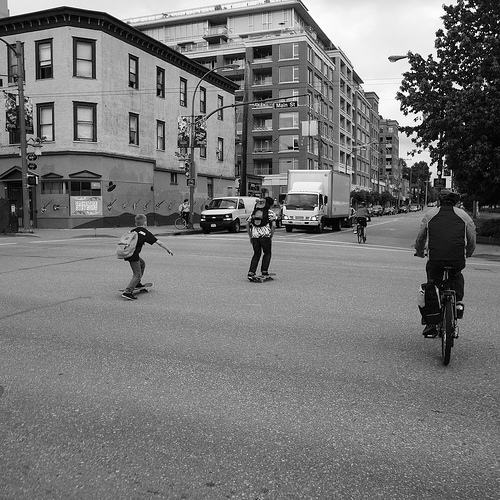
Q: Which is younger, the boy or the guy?
A: The boy is younger than the guy.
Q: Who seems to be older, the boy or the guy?
A: The guy is older than the boy.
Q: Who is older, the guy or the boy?
A: The guy is older than the boy.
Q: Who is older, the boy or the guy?
A: The guy is older than the boy.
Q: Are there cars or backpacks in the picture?
A: Yes, there is a backpack.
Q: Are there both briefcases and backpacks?
A: No, there is a backpack but no briefcases.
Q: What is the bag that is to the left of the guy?
A: The bag is a backpack.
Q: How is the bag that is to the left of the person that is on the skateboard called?
A: The bag is a backpack.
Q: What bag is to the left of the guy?
A: The bag is a backpack.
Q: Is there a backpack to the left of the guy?
A: Yes, there is a backpack to the left of the guy.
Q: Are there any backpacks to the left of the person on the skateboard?
A: Yes, there is a backpack to the left of the guy.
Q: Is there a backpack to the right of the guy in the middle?
A: No, the backpack is to the left of the guy.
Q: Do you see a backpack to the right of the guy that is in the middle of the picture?
A: No, the backpack is to the left of the guy.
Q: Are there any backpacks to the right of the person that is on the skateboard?
A: No, the backpack is to the left of the guy.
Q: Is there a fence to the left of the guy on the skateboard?
A: No, there is a backpack to the left of the guy.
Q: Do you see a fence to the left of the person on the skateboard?
A: No, there is a backpack to the left of the guy.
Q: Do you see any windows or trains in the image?
A: Yes, there is a window.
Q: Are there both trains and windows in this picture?
A: No, there is a window but no trains.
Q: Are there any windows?
A: Yes, there is a window.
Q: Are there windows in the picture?
A: Yes, there is a window.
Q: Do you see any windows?
A: Yes, there is a window.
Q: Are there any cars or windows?
A: Yes, there is a window.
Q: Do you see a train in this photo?
A: No, there are no trains.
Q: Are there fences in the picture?
A: No, there are no fences.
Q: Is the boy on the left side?
A: Yes, the boy is on the left of the image.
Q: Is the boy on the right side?
A: No, the boy is on the left of the image.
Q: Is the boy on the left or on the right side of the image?
A: The boy is on the left of the image.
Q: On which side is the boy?
A: The boy is on the left of the image.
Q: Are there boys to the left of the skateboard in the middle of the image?
A: Yes, there is a boy to the left of the skateboard.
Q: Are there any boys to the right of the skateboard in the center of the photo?
A: No, the boy is to the left of the skateboard.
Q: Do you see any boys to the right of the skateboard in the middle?
A: No, the boy is to the left of the skateboard.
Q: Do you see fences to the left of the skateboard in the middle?
A: No, there is a boy to the left of the skateboard.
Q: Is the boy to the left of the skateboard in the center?
A: Yes, the boy is to the left of the skateboard.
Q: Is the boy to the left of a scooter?
A: No, the boy is to the left of the skateboard.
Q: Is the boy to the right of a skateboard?
A: No, the boy is to the left of a skateboard.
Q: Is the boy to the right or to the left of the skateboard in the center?
A: The boy is to the left of the skateboard.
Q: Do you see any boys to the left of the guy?
A: Yes, there is a boy to the left of the guy.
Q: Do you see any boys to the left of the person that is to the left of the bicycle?
A: Yes, there is a boy to the left of the guy.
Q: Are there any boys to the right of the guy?
A: No, the boy is to the left of the guy.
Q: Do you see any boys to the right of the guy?
A: No, the boy is to the left of the guy.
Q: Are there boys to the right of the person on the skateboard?
A: No, the boy is to the left of the guy.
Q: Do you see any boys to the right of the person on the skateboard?
A: No, the boy is to the left of the guy.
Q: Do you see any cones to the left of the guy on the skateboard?
A: No, there is a boy to the left of the guy.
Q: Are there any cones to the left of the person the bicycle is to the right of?
A: No, there is a boy to the left of the guy.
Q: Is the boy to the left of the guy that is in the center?
A: Yes, the boy is to the left of the guy.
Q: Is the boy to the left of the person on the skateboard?
A: Yes, the boy is to the left of the guy.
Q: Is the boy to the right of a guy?
A: No, the boy is to the left of a guy.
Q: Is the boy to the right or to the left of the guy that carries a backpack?
A: The boy is to the left of the guy.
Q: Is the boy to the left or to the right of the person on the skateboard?
A: The boy is to the left of the guy.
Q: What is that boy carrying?
A: The boy is carrying a backpack.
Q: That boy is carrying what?
A: The boy is carrying a backpack.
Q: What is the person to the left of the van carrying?
A: The boy is carrying a backpack.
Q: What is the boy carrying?
A: The boy is carrying a backpack.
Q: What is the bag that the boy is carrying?
A: The bag is a backpack.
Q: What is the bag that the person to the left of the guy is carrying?
A: The bag is a backpack.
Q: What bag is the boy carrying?
A: The boy is carrying a backpack.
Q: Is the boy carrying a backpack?
A: Yes, the boy is carrying a backpack.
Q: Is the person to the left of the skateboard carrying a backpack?
A: Yes, the boy is carrying a backpack.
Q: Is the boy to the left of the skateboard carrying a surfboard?
A: No, the boy is carrying a backpack.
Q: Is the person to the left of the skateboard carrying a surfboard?
A: No, the boy is carrying a backpack.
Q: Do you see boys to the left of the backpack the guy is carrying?
A: Yes, there is a boy to the left of the backpack.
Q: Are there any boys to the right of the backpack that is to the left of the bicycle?
A: No, the boy is to the left of the backpack.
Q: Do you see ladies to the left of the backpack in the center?
A: No, there is a boy to the left of the backpack.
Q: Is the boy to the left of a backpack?
A: Yes, the boy is to the left of a backpack.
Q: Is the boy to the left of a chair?
A: No, the boy is to the left of a backpack.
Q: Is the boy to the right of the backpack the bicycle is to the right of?
A: No, the boy is to the left of the backpack.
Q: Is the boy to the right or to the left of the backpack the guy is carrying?
A: The boy is to the left of the backpack.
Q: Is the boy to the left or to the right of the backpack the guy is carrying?
A: The boy is to the left of the backpack.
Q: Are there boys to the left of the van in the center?
A: Yes, there is a boy to the left of the van.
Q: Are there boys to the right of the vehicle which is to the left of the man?
A: No, the boy is to the left of the van.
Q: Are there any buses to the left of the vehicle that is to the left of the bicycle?
A: No, there is a boy to the left of the van.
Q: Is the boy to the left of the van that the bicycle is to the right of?
A: Yes, the boy is to the left of the van.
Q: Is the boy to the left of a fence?
A: No, the boy is to the left of the van.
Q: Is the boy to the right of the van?
A: No, the boy is to the left of the van.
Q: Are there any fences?
A: No, there are no fences.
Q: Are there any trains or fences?
A: No, there are no fences or trains.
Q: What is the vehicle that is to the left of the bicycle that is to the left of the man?
A: The vehicle is a van.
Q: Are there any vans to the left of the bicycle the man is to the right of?
A: Yes, there is a van to the left of the bicycle.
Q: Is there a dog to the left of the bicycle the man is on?
A: No, there is a van to the left of the bicycle.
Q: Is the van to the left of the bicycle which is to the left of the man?
A: Yes, the van is to the left of the bicycle.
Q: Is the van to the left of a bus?
A: No, the van is to the left of the bicycle.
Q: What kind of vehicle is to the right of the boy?
A: The vehicle is a van.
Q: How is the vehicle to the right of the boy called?
A: The vehicle is a van.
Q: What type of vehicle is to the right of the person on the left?
A: The vehicle is a van.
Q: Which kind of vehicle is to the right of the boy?
A: The vehicle is a van.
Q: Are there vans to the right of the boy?
A: Yes, there is a van to the right of the boy.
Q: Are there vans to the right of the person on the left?
A: Yes, there is a van to the right of the boy.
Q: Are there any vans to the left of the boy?
A: No, the van is to the right of the boy.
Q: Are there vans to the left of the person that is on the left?
A: No, the van is to the right of the boy.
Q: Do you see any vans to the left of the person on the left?
A: No, the van is to the right of the boy.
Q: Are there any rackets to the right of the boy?
A: No, there is a van to the right of the boy.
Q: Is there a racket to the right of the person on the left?
A: No, there is a van to the right of the boy.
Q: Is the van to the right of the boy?
A: Yes, the van is to the right of the boy.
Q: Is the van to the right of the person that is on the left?
A: Yes, the van is to the right of the boy.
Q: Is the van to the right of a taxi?
A: No, the van is to the right of the boy.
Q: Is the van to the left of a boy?
A: No, the van is to the right of a boy.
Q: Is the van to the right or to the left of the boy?
A: The van is to the right of the boy.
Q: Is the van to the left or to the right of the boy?
A: The van is to the right of the boy.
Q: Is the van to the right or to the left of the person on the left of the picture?
A: The van is to the right of the boy.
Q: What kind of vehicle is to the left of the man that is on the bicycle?
A: The vehicle is a van.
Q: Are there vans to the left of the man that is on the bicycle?
A: Yes, there is a van to the left of the man.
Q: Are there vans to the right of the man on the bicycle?
A: No, the van is to the left of the man.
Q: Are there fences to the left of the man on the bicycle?
A: No, there is a van to the left of the man.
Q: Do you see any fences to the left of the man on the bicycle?
A: No, there is a van to the left of the man.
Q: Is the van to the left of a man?
A: Yes, the van is to the left of a man.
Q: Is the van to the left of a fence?
A: No, the van is to the left of a man.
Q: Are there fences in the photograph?
A: No, there are no fences.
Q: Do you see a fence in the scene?
A: No, there are no fences.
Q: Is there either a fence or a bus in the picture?
A: No, there are no fences or buses.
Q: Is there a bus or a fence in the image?
A: No, there are no fences or buses.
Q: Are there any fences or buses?
A: No, there are no fences or buses.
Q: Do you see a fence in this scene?
A: No, there are no fences.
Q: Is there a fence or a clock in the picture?
A: No, there are no fences or clocks.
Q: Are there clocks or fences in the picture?
A: No, there are no fences or clocks.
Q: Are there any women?
A: No, there are no women.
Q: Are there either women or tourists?
A: No, there are no women or tourists.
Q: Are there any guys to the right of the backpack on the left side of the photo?
A: Yes, there is a guy to the right of the backpack.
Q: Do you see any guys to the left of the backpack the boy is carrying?
A: No, the guy is to the right of the backpack.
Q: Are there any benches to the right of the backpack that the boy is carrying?
A: No, there is a guy to the right of the backpack.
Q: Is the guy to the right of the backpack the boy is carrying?
A: Yes, the guy is to the right of the backpack.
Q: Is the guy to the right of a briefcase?
A: No, the guy is to the right of the backpack.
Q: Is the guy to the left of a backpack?
A: No, the guy is to the right of a backpack.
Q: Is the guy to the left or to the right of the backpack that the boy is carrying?
A: The guy is to the right of the backpack.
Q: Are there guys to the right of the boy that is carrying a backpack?
A: Yes, there is a guy to the right of the boy.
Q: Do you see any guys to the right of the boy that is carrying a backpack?
A: Yes, there is a guy to the right of the boy.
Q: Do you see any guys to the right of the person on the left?
A: Yes, there is a guy to the right of the boy.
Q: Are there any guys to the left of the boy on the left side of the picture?
A: No, the guy is to the right of the boy.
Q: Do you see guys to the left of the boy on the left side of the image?
A: No, the guy is to the right of the boy.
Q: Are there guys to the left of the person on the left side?
A: No, the guy is to the right of the boy.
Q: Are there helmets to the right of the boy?
A: No, there is a guy to the right of the boy.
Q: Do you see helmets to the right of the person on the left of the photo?
A: No, there is a guy to the right of the boy.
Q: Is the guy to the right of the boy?
A: Yes, the guy is to the right of the boy.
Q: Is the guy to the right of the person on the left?
A: Yes, the guy is to the right of the boy.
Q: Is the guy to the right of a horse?
A: No, the guy is to the right of the boy.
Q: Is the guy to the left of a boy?
A: No, the guy is to the right of a boy.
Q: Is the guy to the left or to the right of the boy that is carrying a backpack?
A: The guy is to the right of the boy.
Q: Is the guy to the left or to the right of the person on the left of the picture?
A: The guy is to the right of the boy.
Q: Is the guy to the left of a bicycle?
A: Yes, the guy is to the left of a bicycle.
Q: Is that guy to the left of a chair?
A: No, the guy is to the left of a bicycle.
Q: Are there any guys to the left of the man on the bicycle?
A: Yes, there is a guy to the left of the man.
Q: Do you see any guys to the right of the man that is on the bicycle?
A: No, the guy is to the left of the man.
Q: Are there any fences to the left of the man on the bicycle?
A: No, there is a guy to the left of the man.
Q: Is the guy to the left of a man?
A: Yes, the guy is to the left of a man.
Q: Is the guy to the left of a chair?
A: No, the guy is to the left of a man.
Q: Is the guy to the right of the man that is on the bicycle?
A: No, the guy is to the left of the man.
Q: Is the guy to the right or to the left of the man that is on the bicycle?
A: The guy is to the left of the man.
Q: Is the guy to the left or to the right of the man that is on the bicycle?
A: The guy is to the left of the man.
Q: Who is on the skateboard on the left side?
A: The guy is on the skateboard.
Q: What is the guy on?
A: The guy is on the skateboard.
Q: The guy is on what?
A: The guy is on the skateboard.